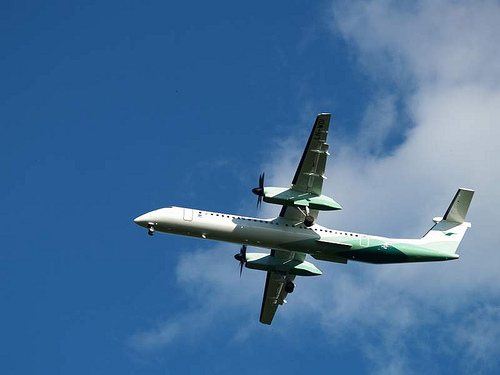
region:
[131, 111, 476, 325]
airplane is white and light green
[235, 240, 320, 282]
far engine with black propeller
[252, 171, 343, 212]
closest engine with black propeller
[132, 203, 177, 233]
airplane with sloping pointy nose and cockpit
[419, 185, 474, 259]
green and white tail with logo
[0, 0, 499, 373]
blue sky has fluffy white clouds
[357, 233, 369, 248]
airplane cabin door on back of plane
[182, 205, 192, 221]
front door on side of plane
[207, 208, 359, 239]
long row of passenger windows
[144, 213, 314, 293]
airplane's landing gear is down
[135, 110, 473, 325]
airplane flying in the air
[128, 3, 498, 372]
white puffy cloud above the airplane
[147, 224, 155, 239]
the airplane's front landing gear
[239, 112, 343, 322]
the airplane's wings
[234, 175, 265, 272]
two black propellers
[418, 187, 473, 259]
the airplane's tail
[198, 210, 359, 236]
passenger windows on the airplane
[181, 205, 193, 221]
front passenger door of the airplane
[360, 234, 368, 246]
rear evacuation door on the airplane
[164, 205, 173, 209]
cockpit window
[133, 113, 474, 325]
the plane in the air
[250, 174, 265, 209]
the propeller on the plane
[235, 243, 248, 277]
the propeller on the plane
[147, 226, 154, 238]
the wheel under the plane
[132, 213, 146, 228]
the nose on the plane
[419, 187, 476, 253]
the tail on the plane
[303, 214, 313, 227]
the wheel under the plane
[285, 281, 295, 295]
the wheel under the plane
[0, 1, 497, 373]
the white clouds in the blue sky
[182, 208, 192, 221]
the door on the plane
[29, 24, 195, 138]
The sky is clear and blue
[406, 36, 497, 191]
The clouds are the color white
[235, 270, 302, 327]
The right wing of the airplane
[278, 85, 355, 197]
The left wing of the airplane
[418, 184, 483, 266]
The back wing of the airplane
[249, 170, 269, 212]
A propeller on the airplane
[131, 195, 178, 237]
The nose of the airplane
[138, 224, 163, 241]
The wheels on the airplane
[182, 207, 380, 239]
The windows on the airplane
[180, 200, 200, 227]
The door on the airplane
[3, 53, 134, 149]
blue sky above the plane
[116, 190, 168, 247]
nose of the plane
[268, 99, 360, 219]
wing of the plane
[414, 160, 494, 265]
tail of the plane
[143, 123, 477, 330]
white plane in photo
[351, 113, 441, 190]
clouds in the sky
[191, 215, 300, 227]
windows on the plane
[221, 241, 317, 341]
right wing of plane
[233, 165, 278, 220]
propellor on the plane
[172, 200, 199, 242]
door of the plane